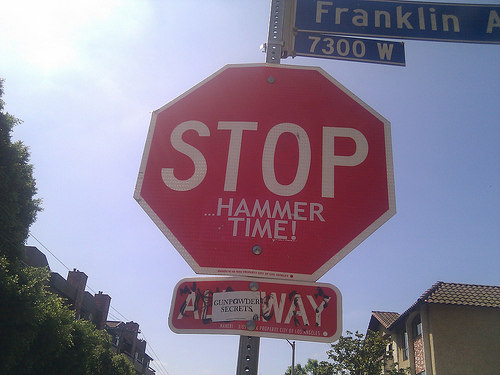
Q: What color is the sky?
A: Blue.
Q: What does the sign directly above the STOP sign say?
A: 7300 W.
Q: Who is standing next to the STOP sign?
A: No one.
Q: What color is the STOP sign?
A: Red.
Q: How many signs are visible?
A: Four.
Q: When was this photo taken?
A: Daytime.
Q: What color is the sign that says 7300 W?
A: Blue.